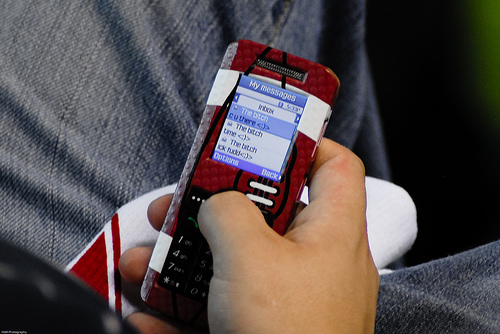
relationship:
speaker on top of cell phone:
[255, 59, 305, 80] [140, 38, 342, 321]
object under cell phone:
[52, 173, 419, 318] [140, 38, 342, 321]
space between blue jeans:
[371, 16, 498, 175] [1, 2, 500, 334]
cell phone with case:
[133, 25, 348, 332] [134, 34, 349, 331]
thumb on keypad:
[194, 189, 292, 256] [160, 189, 265, 312]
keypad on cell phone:
[160, 189, 265, 312] [140, 38, 342, 321]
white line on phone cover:
[204, 66, 333, 150] [141, 40, 341, 318]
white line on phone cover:
[146, 221, 173, 276] [141, 40, 341, 318]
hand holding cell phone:
[114, 134, 383, 332] [140, 38, 342, 321]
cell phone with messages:
[140, 38, 342, 321] [223, 102, 298, 174]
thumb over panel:
[202, 195, 263, 237] [156, 185, 229, 229]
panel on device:
[156, 185, 229, 229] [140, 30, 327, 315]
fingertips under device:
[175, 181, 285, 248] [142, 49, 469, 251]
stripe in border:
[246, 178, 278, 195] [231, 140, 295, 221]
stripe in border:
[244, 188, 278, 208] [231, 140, 295, 221]